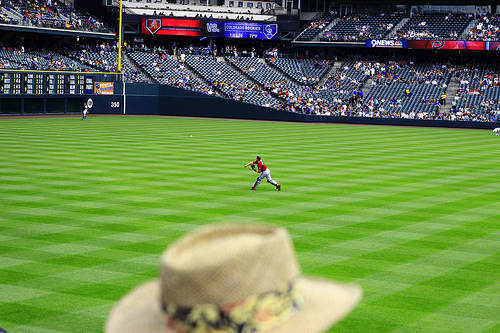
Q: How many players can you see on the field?
A: 2.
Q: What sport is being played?
A: Baseball.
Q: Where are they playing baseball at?
A: A stadium.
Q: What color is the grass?
A: Green.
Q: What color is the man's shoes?
A: Red.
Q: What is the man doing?
A: Throwing a ball.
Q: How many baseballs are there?
A: 1.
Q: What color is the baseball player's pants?
A: Gray.